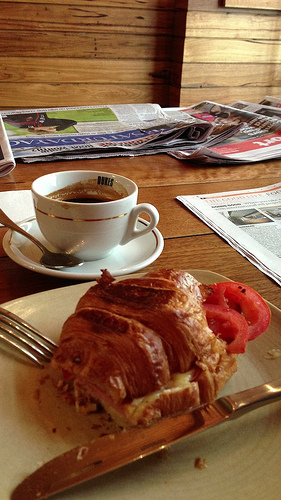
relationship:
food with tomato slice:
[46, 265, 272, 433] [192, 304, 246, 347]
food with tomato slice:
[46, 265, 272, 433] [206, 280, 269, 339]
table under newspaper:
[5, 158, 278, 498] [2, 94, 279, 164]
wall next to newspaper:
[2, 4, 277, 129] [2, 94, 279, 164]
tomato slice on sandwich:
[192, 304, 246, 347] [43, 268, 268, 421]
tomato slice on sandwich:
[206, 280, 269, 339] [43, 268, 268, 421]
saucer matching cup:
[1, 212, 164, 277] [31, 169, 158, 259]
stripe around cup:
[41, 206, 132, 224] [31, 169, 158, 259]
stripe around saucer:
[9, 217, 161, 268] [1, 212, 164, 277]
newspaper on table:
[2, 94, 279, 164] [5, 158, 278, 498]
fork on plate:
[0, 307, 58, 363] [1, 268, 279, 497]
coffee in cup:
[48, 184, 111, 203] [31, 169, 158, 259]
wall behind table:
[2, 4, 277, 129] [5, 158, 278, 498]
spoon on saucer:
[0, 205, 85, 274] [1, 212, 164, 277]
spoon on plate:
[1, 209, 79, 277] [5, 216, 71, 275]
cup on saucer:
[10, 168, 168, 281] [10, 168, 168, 281]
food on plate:
[46, 265, 272, 433] [33, 298, 54, 332]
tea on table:
[6, 172, 276, 414] [171, 218, 194, 257]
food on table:
[6, 172, 276, 414] [171, 218, 194, 257]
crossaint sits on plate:
[34, 270, 260, 422] [36, 300, 55, 325]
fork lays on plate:
[0, 307, 58, 373] [34, 297, 62, 326]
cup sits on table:
[2, 170, 160, 275] [167, 212, 188, 267]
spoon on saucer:
[0, 205, 85, 274] [17, 213, 158, 264]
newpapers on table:
[11, 109, 266, 164] [23, 143, 255, 319]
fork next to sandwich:
[0, 307, 58, 373] [68, 279, 235, 407]